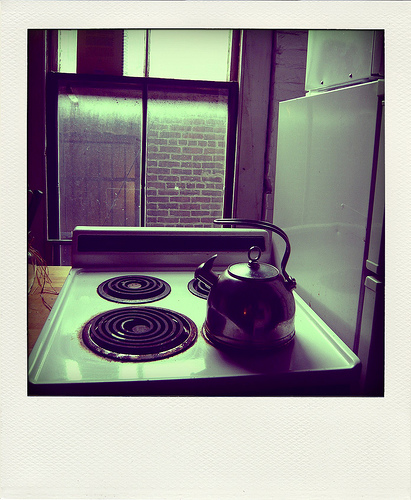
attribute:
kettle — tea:
[193, 212, 305, 365]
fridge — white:
[261, 75, 398, 366]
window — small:
[36, 38, 269, 260]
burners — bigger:
[95, 258, 193, 401]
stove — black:
[26, 223, 360, 398]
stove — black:
[72, 237, 172, 315]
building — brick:
[41, 72, 233, 251]